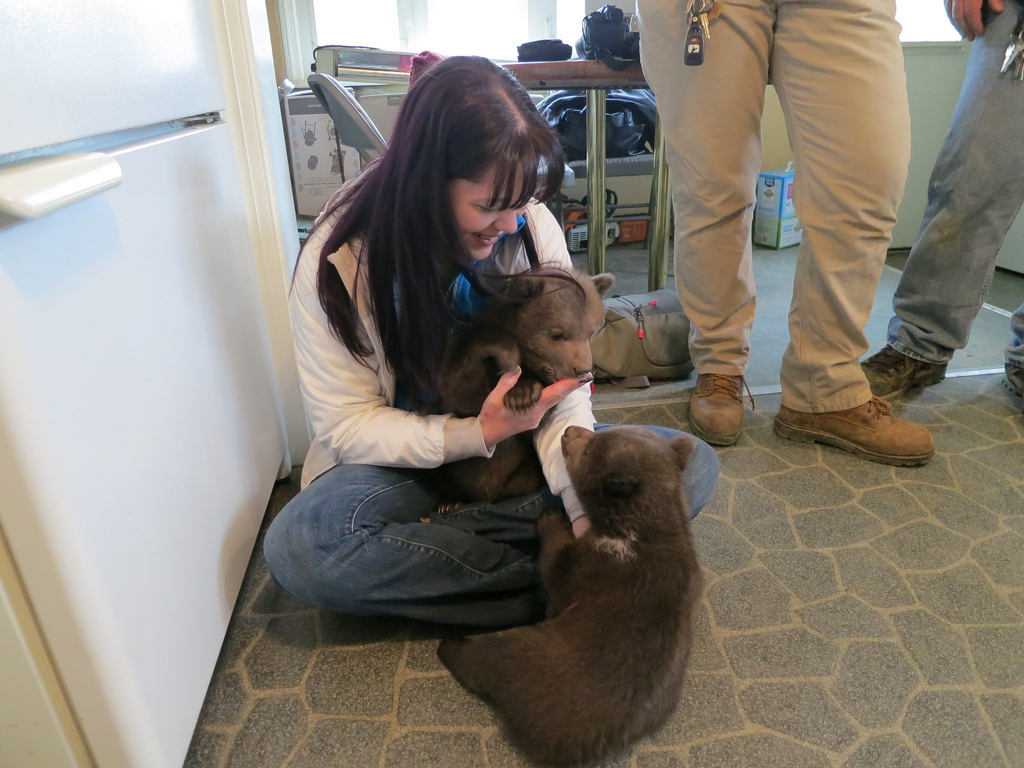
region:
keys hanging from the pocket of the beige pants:
[672, 2, 746, 75]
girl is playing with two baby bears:
[299, 88, 775, 766]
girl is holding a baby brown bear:
[420, 268, 583, 491]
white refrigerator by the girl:
[17, 16, 311, 744]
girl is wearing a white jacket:
[280, 148, 603, 509]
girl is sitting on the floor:
[261, 69, 742, 645]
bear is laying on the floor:
[466, 432, 667, 756]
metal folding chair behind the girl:
[286, 59, 391, 157]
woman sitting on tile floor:
[325, 11, 655, 650]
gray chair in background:
[312, 71, 412, 177]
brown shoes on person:
[660, 367, 939, 472]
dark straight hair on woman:
[336, 71, 567, 366]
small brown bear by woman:
[451, 412, 752, 766]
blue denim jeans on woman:
[268, 500, 756, 663]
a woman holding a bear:
[259, 50, 721, 621]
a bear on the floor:
[430, 426, 770, 766]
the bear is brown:
[420, 418, 705, 766]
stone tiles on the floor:
[705, 464, 1019, 755]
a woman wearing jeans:
[247, 53, 734, 630]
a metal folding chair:
[302, 67, 386, 145]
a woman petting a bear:
[256, 56, 727, 761]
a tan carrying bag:
[587, 288, 690, 381]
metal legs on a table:
[580, 83, 670, 283]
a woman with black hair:
[242, 47, 718, 632]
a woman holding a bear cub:
[274, 44, 766, 608]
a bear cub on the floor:
[462, 436, 735, 756]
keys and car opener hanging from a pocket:
[640, 0, 729, 80]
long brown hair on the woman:
[312, 31, 541, 433]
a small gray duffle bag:
[591, 266, 719, 402]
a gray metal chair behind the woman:
[296, 66, 410, 207]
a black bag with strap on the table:
[571, 3, 647, 81]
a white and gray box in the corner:
[271, 70, 377, 248]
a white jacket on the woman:
[266, 168, 600, 516]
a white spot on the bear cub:
[577, 524, 650, 564]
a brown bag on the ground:
[583, 299, 702, 377]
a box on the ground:
[750, 168, 804, 242]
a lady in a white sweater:
[295, 64, 689, 618]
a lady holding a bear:
[301, 54, 704, 627]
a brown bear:
[446, 424, 704, 761]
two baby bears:
[443, 241, 691, 760]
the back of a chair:
[307, 70, 381, 159]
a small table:
[512, 59, 684, 287]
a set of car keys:
[677, 1, 707, 56]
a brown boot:
[776, 390, 938, 467]